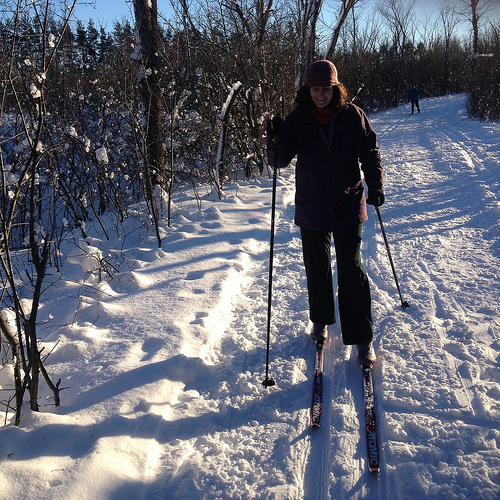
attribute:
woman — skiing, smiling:
[225, 37, 409, 420]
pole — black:
[250, 147, 280, 407]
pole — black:
[370, 188, 415, 318]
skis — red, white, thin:
[300, 339, 382, 500]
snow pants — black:
[289, 228, 381, 344]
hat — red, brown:
[301, 59, 345, 82]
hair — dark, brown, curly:
[278, 83, 350, 111]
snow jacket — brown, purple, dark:
[265, 109, 394, 230]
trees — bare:
[54, 13, 267, 252]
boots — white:
[298, 321, 396, 371]